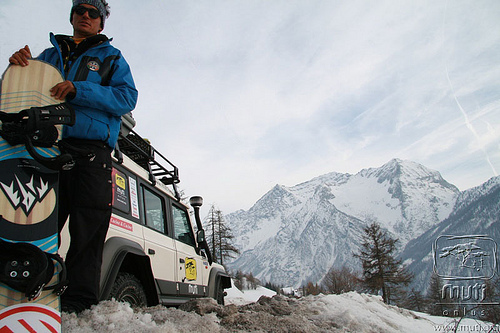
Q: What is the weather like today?
A: It is cloudy.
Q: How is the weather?
A: It is cloudy.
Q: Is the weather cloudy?
A: Yes, it is cloudy.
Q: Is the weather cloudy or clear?
A: It is cloudy.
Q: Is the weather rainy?
A: No, it is cloudy.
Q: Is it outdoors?
A: Yes, it is outdoors.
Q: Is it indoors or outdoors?
A: It is outdoors.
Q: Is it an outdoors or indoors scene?
A: It is outdoors.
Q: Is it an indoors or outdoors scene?
A: It is outdoors.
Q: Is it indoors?
A: No, it is outdoors.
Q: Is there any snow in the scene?
A: Yes, there is snow.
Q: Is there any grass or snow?
A: Yes, there is snow.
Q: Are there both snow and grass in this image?
A: No, there is snow but no grass.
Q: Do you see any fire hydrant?
A: No, there are no fire hydrants.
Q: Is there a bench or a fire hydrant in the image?
A: No, there are no fire hydrants or benches.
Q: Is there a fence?
A: No, there are no fences.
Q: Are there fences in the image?
A: No, there are no fences.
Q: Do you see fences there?
A: No, there are no fences.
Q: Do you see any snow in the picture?
A: Yes, there is snow.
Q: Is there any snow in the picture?
A: Yes, there is snow.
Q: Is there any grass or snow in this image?
A: Yes, there is snow.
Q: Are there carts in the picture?
A: No, there are no carts.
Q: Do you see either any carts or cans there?
A: No, there are no carts or cans.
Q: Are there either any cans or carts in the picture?
A: No, there are no carts or cans.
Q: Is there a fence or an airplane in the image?
A: No, there are no fences or airplanes.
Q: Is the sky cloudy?
A: Yes, the sky is cloudy.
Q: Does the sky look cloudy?
A: Yes, the sky is cloudy.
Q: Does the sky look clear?
A: No, the sky is cloudy.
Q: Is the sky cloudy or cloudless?
A: The sky is cloudy.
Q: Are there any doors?
A: Yes, there is a door.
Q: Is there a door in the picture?
A: Yes, there is a door.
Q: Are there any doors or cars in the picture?
A: Yes, there is a door.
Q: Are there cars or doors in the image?
A: Yes, there is a door.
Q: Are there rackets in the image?
A: No, there are no rackets.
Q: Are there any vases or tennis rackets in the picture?
A: No, there are no tennis rackets or vases.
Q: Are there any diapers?
A: No, there are no diapers.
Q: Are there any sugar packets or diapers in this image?
A: No, there are no diapers or sugar packets.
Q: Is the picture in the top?
A: No, the picture is in the bottom of the image.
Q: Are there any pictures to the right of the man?
A: Yes, there is a picture to the right of the man.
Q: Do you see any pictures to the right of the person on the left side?
A: Yes, there is a picture to the right of the man.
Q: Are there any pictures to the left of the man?
A: No, the picture is to the right of the man.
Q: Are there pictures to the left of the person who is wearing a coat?
A: No, the picture is to the right of the man.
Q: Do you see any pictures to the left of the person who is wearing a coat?
A: No, the picture is to the right of the man.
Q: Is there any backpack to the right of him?
A: No, there is a picture to the right of the man.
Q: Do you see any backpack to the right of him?
A: No, there is a picture to the right of the man.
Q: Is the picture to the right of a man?
A: Yes, the picture is to the right of a man.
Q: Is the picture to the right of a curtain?
A: No, the picture is to the right of a man.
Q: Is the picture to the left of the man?
A: No, the picture is to the right of the man.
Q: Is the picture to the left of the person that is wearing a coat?
A: No, the picture is to the right of the man.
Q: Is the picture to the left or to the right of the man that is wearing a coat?
A: The picture is to the right of the man.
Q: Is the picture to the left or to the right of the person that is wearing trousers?
A: The picture is to the right of the man.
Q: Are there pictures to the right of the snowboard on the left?
A: Yes, there is a picture to the right of the snow board.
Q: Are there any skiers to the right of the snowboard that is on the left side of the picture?
A: No, there is a picture to the right of the snowboard.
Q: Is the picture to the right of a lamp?
A: No, the picture is to the right of the snow board.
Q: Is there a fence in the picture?
A: No, there are no fences.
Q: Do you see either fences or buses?
A: No, there are no fences or buses.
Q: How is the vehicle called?
A: The vehicle is a car.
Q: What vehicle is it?
A: The vehicle is a car.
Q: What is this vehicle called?
A: This is a car.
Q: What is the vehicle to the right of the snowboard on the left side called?
A: The vehicle is a car.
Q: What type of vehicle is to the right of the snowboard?
A: The vehicle is a car.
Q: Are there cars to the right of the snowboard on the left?
A: Yes, there is a car to the right of the snow board.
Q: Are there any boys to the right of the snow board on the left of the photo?
A: No, there is a car to the right of the snowboard.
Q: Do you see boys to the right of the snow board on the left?
A: No, there is a car to the right of the snowboard.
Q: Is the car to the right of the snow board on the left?
A: Yes, the car is to the right of the snow board.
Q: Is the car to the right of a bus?
A: No, the car is to the right of the snow board.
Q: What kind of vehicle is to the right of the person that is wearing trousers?
A: The vehicle is a car.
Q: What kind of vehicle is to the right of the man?
A: The vehicle is a car.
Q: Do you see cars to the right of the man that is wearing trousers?
A: Yes, there is a car to the right of the man.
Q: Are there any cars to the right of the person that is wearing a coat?
A: Yes, there is a car to the right of the man.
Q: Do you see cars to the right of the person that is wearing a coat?
A: Yes, there is a car to the right of the man.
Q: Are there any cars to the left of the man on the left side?
A: No, the car is to the right of the man.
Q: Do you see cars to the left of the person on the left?
A: No, the car is to the right of the man.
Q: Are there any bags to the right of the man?
A: No, there is a car to the right of the man.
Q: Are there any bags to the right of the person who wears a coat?
A: No, there is a car to the right of the man.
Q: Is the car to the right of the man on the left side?
A: Yes, the car is to the right of the man.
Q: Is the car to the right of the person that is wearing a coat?
A: Yes, the car is to the right of the man.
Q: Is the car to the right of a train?
A: No, the car is to the right of the man.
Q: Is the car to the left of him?
A: No, the car is to the right of a man.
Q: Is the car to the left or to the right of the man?
A: The car is to the right of the man.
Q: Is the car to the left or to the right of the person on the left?
A: The car is to the right of the man.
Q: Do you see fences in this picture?
A: No, there are no fences.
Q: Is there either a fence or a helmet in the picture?
A: No, there are no fences or helmets.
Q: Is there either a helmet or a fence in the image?
A: No, there are no fences or helmets.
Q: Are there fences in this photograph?
A: No, there are no fences.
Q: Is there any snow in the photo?
A: Yes, there is snow.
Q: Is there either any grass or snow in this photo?
A: Yes, there is snow.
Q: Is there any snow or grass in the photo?
A: Yes, there is snow.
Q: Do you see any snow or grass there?
A: Yes, there is snow.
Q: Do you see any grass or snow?
A: Yes, there is snow.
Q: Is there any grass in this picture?
A: No, there is no grass.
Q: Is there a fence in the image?
A: No, there are no fences.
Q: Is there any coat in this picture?
A: Yes, there is a coat.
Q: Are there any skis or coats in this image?
A: Yes, there is a coat.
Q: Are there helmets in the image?
A: No, there are no helmets.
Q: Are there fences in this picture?
A: No, there are no fences.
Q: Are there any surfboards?
A: No, there are no surfboards.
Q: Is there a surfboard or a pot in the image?
A: No, there are no surfboards or pots.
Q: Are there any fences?
A: No, there are no fences.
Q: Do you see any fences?
A: No, there are no fences.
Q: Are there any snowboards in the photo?
A: Yes, there is a snowboard.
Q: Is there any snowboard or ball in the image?
A: Yes, there is a snowboard.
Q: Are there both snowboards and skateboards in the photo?
A: No, there is a snowboard but no skateboards.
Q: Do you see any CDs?
A: No, there are no cds.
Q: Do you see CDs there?
A: No, there are no cds.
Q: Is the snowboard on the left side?
A: Yes, the snowboard is on the left of the image.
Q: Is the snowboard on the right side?
A: No, the snowboard is on the left of the image.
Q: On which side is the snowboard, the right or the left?
A: The snowboard is on the left of the image.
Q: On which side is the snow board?
A: The snow board is on the left of the image.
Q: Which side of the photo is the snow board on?
A: The snow board is on the left of the image.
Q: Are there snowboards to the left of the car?
A: Yes, there is a snowboard to the left of the car.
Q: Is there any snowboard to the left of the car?
A: Yes, there is a snowboard to the left of the car.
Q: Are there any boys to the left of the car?
A: No, there is a snowboard to the left of the car.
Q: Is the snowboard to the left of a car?
A: Yes, the snowboard is to the left of a car.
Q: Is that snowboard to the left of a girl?
A: No, the snowboard is to the left of a car.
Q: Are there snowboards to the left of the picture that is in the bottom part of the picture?
A: Yes, there is a snowboard to the left of the picture.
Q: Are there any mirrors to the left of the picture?
A: No, there is a snowboard to the left of the picture.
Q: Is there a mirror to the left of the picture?
A: No, there is a snowboard to the left of the picture.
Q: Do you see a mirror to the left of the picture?
A: No, there is a snowboard to the left of the picture.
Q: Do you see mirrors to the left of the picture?
A: No, there is a snowboard to the left of the picture.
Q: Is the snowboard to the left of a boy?
A: No, the snowboard is to the left of the picture.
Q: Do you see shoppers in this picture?
A: No, there are no shoppers.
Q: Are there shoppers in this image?
A: No, there are no shoppers.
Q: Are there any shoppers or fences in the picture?
A: No, there are no shoppers or fences.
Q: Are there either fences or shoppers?
A: No, there are no shoppers or fences.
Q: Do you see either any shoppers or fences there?
A: No, there are no shoppers or fences.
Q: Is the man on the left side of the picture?
A: Yes, the man is on the left of the image.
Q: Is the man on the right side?
A: No, the man is on the left of the image.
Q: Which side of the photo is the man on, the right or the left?
A: The man is on the left of the image.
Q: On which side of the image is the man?
A: The man is on the left of the image.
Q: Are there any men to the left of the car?
A: Yes, there is a man to the left of the car.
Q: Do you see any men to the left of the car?
A: Yes, there is a man to the left of the car.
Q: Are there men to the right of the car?
A: No, the man is to the left of the car.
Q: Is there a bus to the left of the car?
A: No, there is a man to the left of the car.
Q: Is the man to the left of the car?
A: Yes, the man is to the left of the car.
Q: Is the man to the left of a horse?
A: No, the man is to the left of the car.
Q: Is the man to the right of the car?
A: No, the man is to the left of the car.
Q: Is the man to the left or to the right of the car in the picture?
A: The man is to the left of the car.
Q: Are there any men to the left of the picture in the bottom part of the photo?
A: Yes, there is a man to the left of the picture.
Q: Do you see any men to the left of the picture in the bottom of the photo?
A: Yes, there is a man to the left of the picture.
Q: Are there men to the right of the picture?
A: No, the man is to the left of the picture.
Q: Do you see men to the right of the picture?
A: No, the man is to the left of the picture.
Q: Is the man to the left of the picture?
A: Yes, the man is to the left of the picture.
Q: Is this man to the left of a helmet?
A: No, the man is to the left of the picture.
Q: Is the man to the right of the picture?
A: No, the man is to the left of the picture.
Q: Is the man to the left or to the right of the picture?
A: The man is to the left of the picture.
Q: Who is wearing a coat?
A: The man is wearing a coat.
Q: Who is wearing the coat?
A: The man is wearing a coat.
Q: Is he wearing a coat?
A: Yes, the man is wearing a coat.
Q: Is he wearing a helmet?
A: No, the man is wearing a coat.